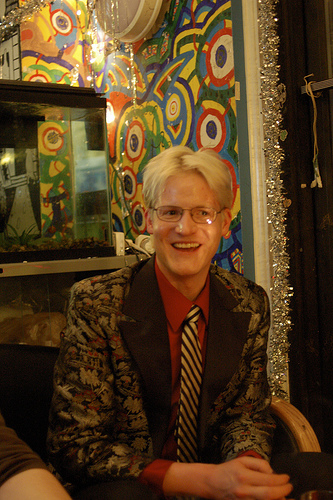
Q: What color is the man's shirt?
A: Red.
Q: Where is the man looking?
A: Ahead.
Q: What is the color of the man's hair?
A: Blonde.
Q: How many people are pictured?
A: One.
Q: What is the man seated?
A: A chair.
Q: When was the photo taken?
A: At night.